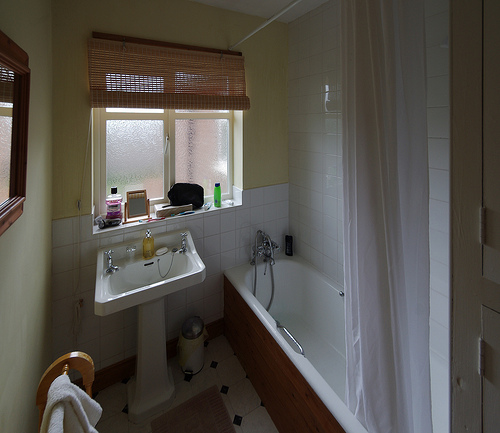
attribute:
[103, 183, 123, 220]
bottle — clear, plastic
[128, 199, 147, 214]
mirror — small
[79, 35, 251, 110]
window shade — bamboo wood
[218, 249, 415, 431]
bath tub — porcelain, white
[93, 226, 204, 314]
sink — white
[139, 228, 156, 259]
soap —  liquid , yellow  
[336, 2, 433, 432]
shower curtain — white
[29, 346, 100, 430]
rack — wood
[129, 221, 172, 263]
hand soap — liquid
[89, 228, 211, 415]
sink — white, porcelain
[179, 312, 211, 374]
basket — white, chrome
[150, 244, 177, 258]
soap — white